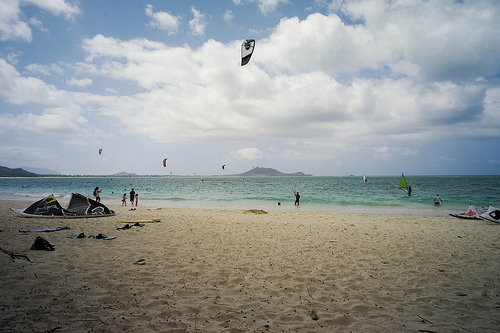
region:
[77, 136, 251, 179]
several kites in the distance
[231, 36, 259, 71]
blue and white kite in the sky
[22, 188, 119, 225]
black tent set up on beach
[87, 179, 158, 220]
group of people on the beach near a tent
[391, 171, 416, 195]
yellow sail in the water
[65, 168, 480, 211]
blue green ocean water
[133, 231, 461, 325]
white sandy beach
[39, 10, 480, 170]
blue sky with white clouds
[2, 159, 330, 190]
mountains in the distance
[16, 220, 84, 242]
blue surfboard laying in sand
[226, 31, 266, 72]
a kite in the sky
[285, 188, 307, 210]
a person in the water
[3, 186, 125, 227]
a tent on the beach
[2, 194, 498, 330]
a brown sandy beach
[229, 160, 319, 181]
a mountain in the distance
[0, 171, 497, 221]
calm blue waters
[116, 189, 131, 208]
a child on the beach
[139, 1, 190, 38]
a white cloud overhead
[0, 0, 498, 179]
a cloudy blue sky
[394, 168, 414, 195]
a green surfboard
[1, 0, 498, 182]
a blue cloudy sky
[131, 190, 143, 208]
a child on the beach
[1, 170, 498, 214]
calm ocean waters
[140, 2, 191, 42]
a white cloud in the sky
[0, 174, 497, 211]
blue water on the beach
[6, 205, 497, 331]
a sandy brown beach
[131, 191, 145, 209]
a child at the edge of the water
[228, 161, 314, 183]
a hill in the distance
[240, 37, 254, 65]
kite surfing kite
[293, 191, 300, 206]
a person on the beach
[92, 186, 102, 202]
a person on the beach.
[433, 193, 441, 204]
A person in the water.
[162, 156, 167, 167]
A kite surfing kite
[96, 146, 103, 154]
A kite surfing kite.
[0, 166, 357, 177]
A land in the distance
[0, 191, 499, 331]
beach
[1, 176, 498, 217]
A large body of water.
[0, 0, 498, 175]
The sky